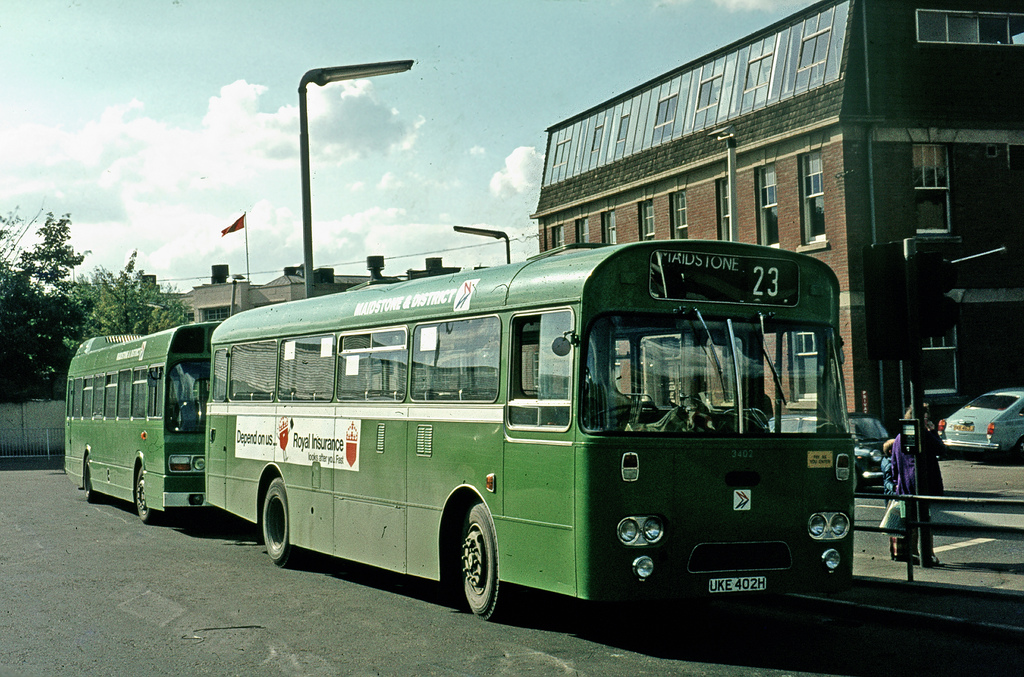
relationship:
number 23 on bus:
[754, 261, 788, 306] [203, 245, 861, 606]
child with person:
[881, 436, 902, 496] [892, 401, 946, 566]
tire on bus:
[455, 507, 500, 621] [203, 245, 861, 606]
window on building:
[798, 151, 836, 250] [587, 75, 1000, 244]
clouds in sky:
[184, 97, 284, 195] [95, 30, 294, 188]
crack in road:
[954, 599, 990, 654] [72, 597, 374, 675]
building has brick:
[587, 75, 1000, 244] [833, 185, 857, 248]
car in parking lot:
[951, 380, 1022, 454] [941, 456, 1022, 511]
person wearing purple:
[888, 398, 950, 567] [896, 437, 932, 493]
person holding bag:
[888, 398, 950, 567] [876, 499, 903, 539]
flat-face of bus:
[602, 249, 845, 602] [203, 245, 861, 606]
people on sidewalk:
[888, 398, 950, 567] [927, 563, 1015, 594]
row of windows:
[644, 35, 826, 126] [676, 49, 811, 139]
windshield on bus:
[604, 311, 837, 444] [203, 245, 861, 606]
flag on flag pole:
[220, 207, 257, 239] [243, 231, 261, 275]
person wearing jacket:
[888, 398, 950, 567] [896, 431, 949, 497]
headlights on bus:
[620, 509, 667, 555] [203, 245, 861, 606]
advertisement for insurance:
[235, 407, 372, 482] [308, 436, 349, 456]